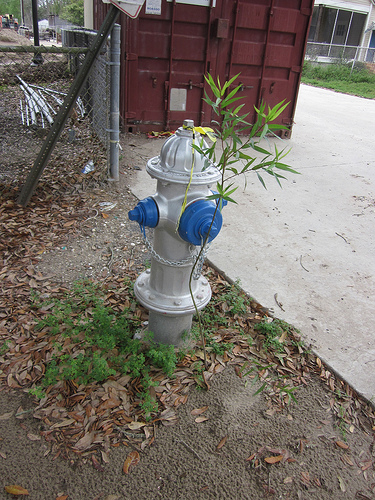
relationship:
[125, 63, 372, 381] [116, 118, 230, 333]
driveway next to hydrant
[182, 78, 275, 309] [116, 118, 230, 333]
plant beside hydrant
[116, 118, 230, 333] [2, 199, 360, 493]
hydrant on ground